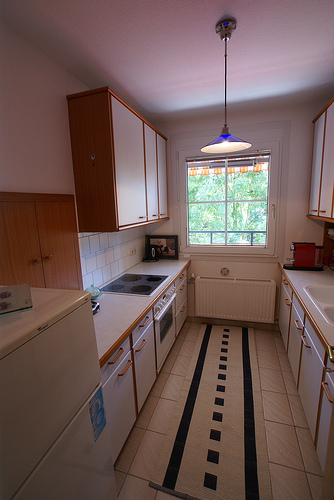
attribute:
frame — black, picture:
[144, 237, 180, 258]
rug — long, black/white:
[156, 302, 272, 498]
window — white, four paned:
[180, 158, 280, 251]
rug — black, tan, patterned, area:
[163, 367, 267, 498]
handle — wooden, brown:
[127, 336, 162, 371]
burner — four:
[127, 282, 152, 296]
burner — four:
[144, 271, 164, 286]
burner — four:
[120, 271, 143, 284]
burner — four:
[103, 281, 126, 293]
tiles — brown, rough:
[236, 340, 319, 470]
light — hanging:
[200, 18, 251, 155]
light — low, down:
[197, 10, 256, 160]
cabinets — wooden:
[65, 84, 170, 232]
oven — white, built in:
[115, 260, 185, 353]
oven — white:
[122, 282, 171, 341]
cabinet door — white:
[94, 88, 175, 225]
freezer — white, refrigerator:
[45, 287, 96, 380]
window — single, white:
[181, 146, 276, 250]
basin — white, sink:
[273, 260, 333, 331]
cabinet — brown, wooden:
[5, 190, 76, 287]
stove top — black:
[97, 271, 172, 298]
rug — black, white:
[148, 321, 272, 498]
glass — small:
[80, 277, 120, 330]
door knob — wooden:
[44, 252, 52, 261]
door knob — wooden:
[32, 255, 42, 264]